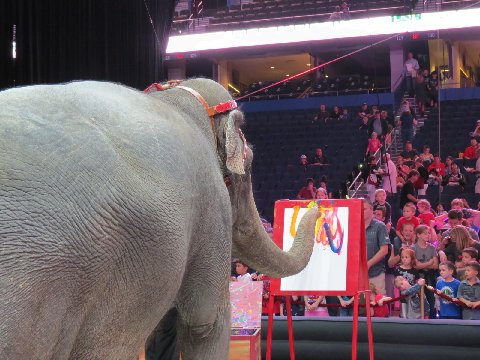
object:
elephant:
[0, 76, 318, 360]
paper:
[277, 204, 349, 294]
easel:
[265, 195, 370, 300]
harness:
[142, 72, 241, 125]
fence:
[261, 315, 480, 360]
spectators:
[393, 197, 419, 244]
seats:
[278, 181, 294, 192]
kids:
[414, 197, 437, 225]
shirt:
[364, 138, 382, 155]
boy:
[454, 261, 479, 320]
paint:
[287, 201, 325, 244]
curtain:
[0, 0, 163, 83]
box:
[229, 321, 262, 359]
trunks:
[216, 169, 329, 280]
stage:
[223, 336, 378, 360]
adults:
[347, 194, 392, 319]